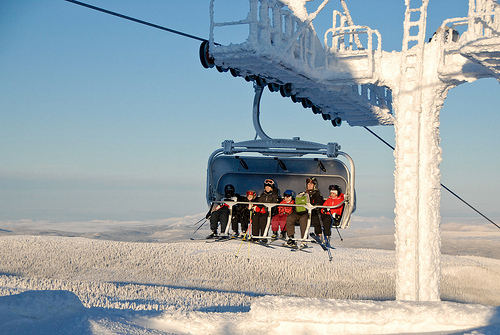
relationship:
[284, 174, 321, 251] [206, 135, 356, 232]
person on lift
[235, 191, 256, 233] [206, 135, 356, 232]
child on lift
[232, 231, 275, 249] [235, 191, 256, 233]
ski on child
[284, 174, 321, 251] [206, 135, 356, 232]
person sitting on lift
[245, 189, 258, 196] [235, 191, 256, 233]
goggle on child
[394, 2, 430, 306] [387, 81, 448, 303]
ladder on pillar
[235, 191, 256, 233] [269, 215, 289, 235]
child in pants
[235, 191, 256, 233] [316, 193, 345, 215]
child wearing jacket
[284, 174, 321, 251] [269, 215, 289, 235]
person in pants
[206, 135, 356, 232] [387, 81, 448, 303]
lift by pillar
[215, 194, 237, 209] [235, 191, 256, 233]
shirt on child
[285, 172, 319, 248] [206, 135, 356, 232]
skier on lift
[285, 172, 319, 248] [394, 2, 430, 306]
skier by ladder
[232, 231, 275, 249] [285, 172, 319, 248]
ski on skier